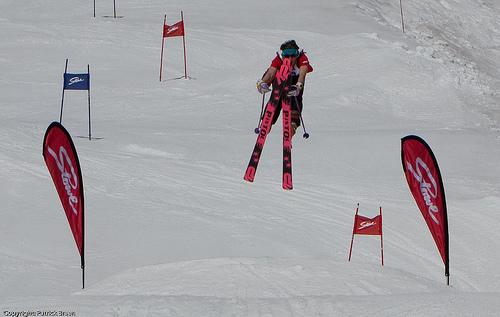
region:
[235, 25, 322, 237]
person jumping with skis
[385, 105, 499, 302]
red advertisement flag in snow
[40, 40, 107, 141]
blue track advertisement for skiing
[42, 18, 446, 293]
person doing tricks while skiing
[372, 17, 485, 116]
piles of snow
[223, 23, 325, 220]
bright pink skis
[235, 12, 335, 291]
person jumping skiis with brown hair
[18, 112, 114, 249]
Stowe advertisement in red and white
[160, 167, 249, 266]
snow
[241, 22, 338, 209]
blue headband on a skier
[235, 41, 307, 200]
Pink on the bottom of the skis.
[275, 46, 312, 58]
Blue headband on the skier.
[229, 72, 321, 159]
Ski poles in the skier's hands.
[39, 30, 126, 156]
Single blue flag.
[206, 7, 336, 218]
Skier in the air from a jump.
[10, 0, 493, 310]
Snow on the ground.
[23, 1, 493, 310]
White ground from the snow.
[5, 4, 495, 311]
Winter time scene.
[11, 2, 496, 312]
Photo taken during the day.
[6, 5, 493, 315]
Photo taken at a ski mountain.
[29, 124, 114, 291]
a red flag marking the snow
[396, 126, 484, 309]
a red marker in the snow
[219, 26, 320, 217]
a man performing a stunt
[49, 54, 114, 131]
a blue flag in the snow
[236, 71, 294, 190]
hot pink and black skis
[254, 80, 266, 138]
a hand grasping a ski pole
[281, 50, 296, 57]
sunglasses on a face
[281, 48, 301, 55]
a blue head band on a head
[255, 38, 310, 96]
a man wearing a red and white shirt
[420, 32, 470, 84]
tracks in the icy snow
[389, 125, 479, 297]
a reg flag in the snow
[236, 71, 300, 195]
a pair of hot pink and black skis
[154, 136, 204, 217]
tracks in the icy white snow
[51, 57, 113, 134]
a blue sign in the snow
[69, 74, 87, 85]
white writing on the sign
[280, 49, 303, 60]
black sunglasses on eyes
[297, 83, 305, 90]
wrist band on a wrist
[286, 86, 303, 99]
a hand grasping a ski pole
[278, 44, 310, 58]
a blue bandana around a forehead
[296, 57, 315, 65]
red sleeve on shirt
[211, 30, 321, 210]
skier jumping in the air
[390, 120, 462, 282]
tear-drop shaped banner in the snow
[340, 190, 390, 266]
red gate against white snow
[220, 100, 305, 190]
bottom of skis are pink and black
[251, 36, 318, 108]
skier wearing short sleeves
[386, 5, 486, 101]
snow in clusters and mounds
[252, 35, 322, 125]
arms straightened in front of body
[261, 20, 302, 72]
wide headband around forehead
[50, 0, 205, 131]
series of ski gates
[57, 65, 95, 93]
writing on fabric of gate